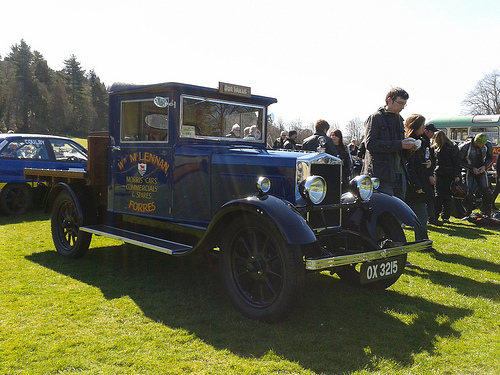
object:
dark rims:
[53, 190, 305, 322]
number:
[370, 262, 379, 284]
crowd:
[239, 87, 490, 264]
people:
[227, 125, 257, 137]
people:
[283, 130, 296, 150]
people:
[302, 120, 337, 174]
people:
[364, 87, 413, 264]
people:
[461, 132, 493, 222]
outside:
[1, 1, 498, 373]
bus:
[424, 116, 497, 144]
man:
[362, 87, 419, 243]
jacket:
[355, 105, 413, 185]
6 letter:
[365, 260, 399, 279]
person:
[359, 81, 418, 246]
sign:
[114, 152, 169, 215]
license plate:
[359, 262, 413, 281]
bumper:
[305, 239, 444, 271]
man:
[460, 133, 496, 218]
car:
[1, 130, 89, 217]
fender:
[186, 195, 318, 249]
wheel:
[211, 214, 300, 320]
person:
[359, 82, 412, 206]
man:
[360, 77, 423, 201]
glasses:
[392, 99, 410, 107]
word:
[116, 157, 128, 171]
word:
[129, 150, 169, 174]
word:
[122, 175, 143, 185]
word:
[124, 183, 160, 192]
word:
[125, 199, 157, 214]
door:
[109, 91, 177, 219]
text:
[117, 150, 170, 212]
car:
[43, 80, 430, 322]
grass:
[33, 114, 490, 363]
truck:
[35, 72, 405, 310]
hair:
[386, 87, 409, 105]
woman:
[403, 110, 435, 247]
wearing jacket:
[403, 133, 436, 209]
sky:
[0, 3, 491, 88]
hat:
[474, 130, 488, 144]